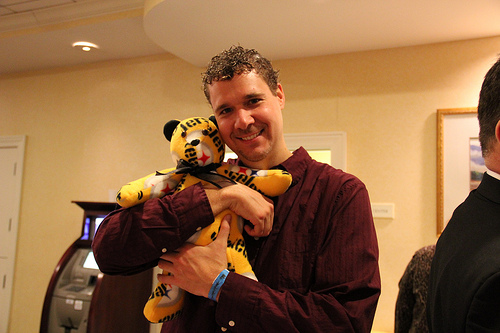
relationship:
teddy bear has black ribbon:
[115, 114, 293, 326] [153, 156, 235, 188]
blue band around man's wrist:
[203, 266, 231, 304] [201, 264, 246, 309]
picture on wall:
[432, 106, 484, 236] [0, 37, 499, 328]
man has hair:
[85, 33, 389, 331] [192, 41, 280, 98]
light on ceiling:
[69, 35, 104, 59] [0, 2, 500, 77]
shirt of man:
[89, 146, 381, 331] [85, 33, 389, 331]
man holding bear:
[85, 33, 389, 331] [114, 112, 291, 318]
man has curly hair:
[85, 33, 389, 331] [200, 39, 284, 91]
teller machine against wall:
[30, 194, 105, 330] [10, 48, 458, 329]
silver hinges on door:
[4, 155, 20, 297] [1, 134, 28, 331]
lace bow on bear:
[152, 157, 224, 176] [114, 112, 291, 318]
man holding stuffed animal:
[85, 33, 389, 331] [117, 115, 294, 326]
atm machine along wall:
[38, 199, 136, 331] [46, 62, 194, 192]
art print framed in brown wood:
[429, 101, 485, 238] [430, 106, 447, 239]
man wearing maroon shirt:
[85, 33, 389, 331] [80, 144, 382, 331]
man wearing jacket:
[424, 51, 497, 329] [423, 169, 495, 329]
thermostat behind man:
[370, 198, 397, 221] [85, 33, 389, 331]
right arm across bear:
[92, 175, 274, 273] [114, 112, 291, 318]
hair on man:
[200, 44, 281, 104] [85, 33, 389, 331]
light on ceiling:
[72, 40, 99, 51] [0, 2, 500, 77]